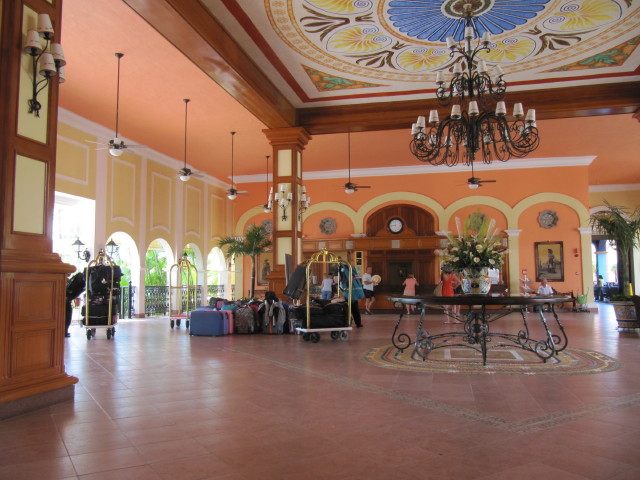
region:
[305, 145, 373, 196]
orange walls in room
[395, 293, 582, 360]
black and iron table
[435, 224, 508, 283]
large vase of flowers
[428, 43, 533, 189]
black chandelier over table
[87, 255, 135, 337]
tall cart with black luggage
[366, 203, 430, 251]
white clock on wall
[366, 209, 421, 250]
black frame on clock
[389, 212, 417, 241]
white face on clock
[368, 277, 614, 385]
a large round table made of wood and iron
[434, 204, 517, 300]
a huge glass vase holding flowers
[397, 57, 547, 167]
a huge black iron chandalier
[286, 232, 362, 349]
a trolley for carrying luggage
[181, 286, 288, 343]
a lot of luggage on floor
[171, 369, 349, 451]
terra cotta tiles on floor of lobby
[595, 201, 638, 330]
a palm tree in a hotel lobby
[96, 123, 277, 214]
four matching ceiling fans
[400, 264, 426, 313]
a woman at the hotel desk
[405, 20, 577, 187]
this is an iron chandalier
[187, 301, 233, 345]
a purple suitcase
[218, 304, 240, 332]
this is a pink suitcase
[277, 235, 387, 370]
there is luggage on this cart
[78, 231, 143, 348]
luggage is stacked on this cart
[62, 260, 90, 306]
luggage being placed on the cart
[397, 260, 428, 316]
she is wearing a pink shirt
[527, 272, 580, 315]
this man is sitting on a bench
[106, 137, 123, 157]
light hanging in the lobby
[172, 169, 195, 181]
light hanging in the lobby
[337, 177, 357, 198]
light hanging in the lobby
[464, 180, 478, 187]
light hanging in the lobby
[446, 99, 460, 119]
light hanging in the lobby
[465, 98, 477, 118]
light hanging in the lobby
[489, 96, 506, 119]
light hanging in the lobby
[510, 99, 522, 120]
light hanging in the lobby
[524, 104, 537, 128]
light hanging in the lobby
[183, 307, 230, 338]
The suitcase is blue in color.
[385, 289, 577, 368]
The table is round in shape.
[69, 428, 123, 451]
the tile is red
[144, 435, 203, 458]
the tile is red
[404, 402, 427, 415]
the tile is red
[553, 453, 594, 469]
the tile is red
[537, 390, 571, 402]
the tile is red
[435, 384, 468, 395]
the tile is red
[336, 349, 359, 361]
the tile is red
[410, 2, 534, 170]
chandelier hanging from ceiling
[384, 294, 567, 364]
the table is metal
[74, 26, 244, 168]
a ceiling that is pink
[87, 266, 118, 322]
suitcases that are black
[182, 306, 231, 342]
a suitcase that is blue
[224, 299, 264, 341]
a suitcase that is tan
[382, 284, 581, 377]
a table that is black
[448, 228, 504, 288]
a plant that is on a table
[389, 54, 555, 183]
a chandelier that is hanging